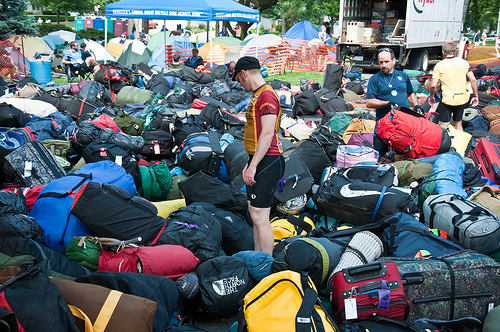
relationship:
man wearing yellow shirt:
[425, 40, 481, 138] [428, 58, 480, 110]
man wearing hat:
[362, 42, 420, 159] [215, 55, 270, 81]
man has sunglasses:
[362, 42, 420, 159] [375, 46, 394, 59]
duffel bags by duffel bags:
[4, 137, 66, 187] [0, 65, 498, 330]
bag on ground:
[178, 126, 225, 176] [11, 62, 498, 324]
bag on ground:
[375, 109, 452, 160] [11, 62, 498, 324]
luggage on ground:
[72, 174, 173, 243] [11, 62, 498, 324]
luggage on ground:
[111, 81, 161, 106] [11, 62, 498, 324]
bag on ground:
[330, 259, 412, 316] [11, 62, 498, 324]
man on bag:
[227, 52, 289, 257] [322, 172, 412, 226]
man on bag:
[362, 42, 425, 159] [375, 109, 452, 160]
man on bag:
[425, 36, 483, 138] [375, 109, 452, 160]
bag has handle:
[330, 259, 412, 316] [349, 257, 384, 284]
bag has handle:
[330, 259, 412, 316] [345, 261, 383, 276]